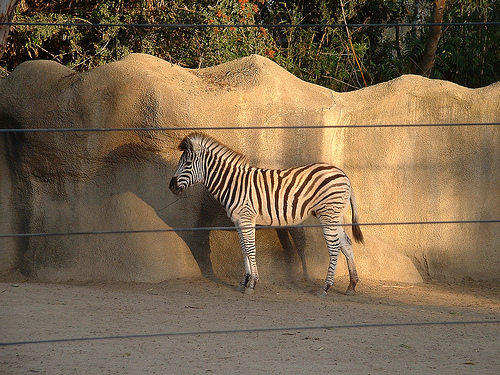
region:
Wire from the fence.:
[2, 209, 499, 247]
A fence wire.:
[5, 116, 499, 139]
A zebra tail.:
[345, 188, 366, 241]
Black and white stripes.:
[245, 166, 310, 226]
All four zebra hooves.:
[235, 282, 360, 302]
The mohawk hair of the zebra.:
[176, 129, 250, 167]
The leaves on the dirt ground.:
[278, 329, 489, 374]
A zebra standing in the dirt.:
[159, 127, 381, 304]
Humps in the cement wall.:
[9, 45, 498, 139]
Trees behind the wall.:
[3, 0, 498, 92]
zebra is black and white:
[164, 136, 387, 293]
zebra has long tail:
[348, 181, 365, 261]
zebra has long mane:
[178, 133, 251, 166]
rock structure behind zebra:
[13, 66, 499, 309]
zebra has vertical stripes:
[198, 134, 356, 239]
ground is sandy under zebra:
[1, 287, 481, 364]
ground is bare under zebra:
[15, 280, 480, 371]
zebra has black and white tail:
[344, 179, 363, 249]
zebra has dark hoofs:
[234, 254, 362, 304]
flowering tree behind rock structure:
[201, 4, 292, 64]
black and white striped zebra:
[167, 119, 396, 310]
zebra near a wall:
[157, 120, 388, 300]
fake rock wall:
[13, 58, 174, 308]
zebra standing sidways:
[146, 125, 416, 315]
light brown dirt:
[13, 288, 148, 333]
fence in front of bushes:
[3, 5, 125, 267]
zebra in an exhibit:
[62, 68, 444, 328]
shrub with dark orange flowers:
[188, 0, 279, 57]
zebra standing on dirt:
[165, 130, 397, 315]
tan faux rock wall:
[369, 76, 495, 328]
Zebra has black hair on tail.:
[350, 217, 367, 251]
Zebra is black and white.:
[216, 165, 350, 274]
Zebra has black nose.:
[169, 180, 189, 207]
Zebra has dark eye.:
[188, 159, 198, 187]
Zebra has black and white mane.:
[186, 126, 246, 190]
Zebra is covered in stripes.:
[198, 135, 331, 252]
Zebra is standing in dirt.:
[166, 239, 416, 324]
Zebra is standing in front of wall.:
[161, 117, 358, 272]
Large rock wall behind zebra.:
[70, 86, 492, 271]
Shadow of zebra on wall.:
[93, 119, 159, 241]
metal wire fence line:
[5, 119, 499, 131]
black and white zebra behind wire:
[168, 128, 383, 299]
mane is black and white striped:
[185, 132, 256, 169]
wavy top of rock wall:
[12, 53, 498, 116]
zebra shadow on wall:
[85, 147, 240, 273]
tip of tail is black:
[350, 215, 368, 246]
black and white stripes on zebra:
[220, 172, 338, 209]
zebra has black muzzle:
[165, 172, 188, 199]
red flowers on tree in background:
[207, 6, 284, 58]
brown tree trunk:
[426, 1, 446, 76]